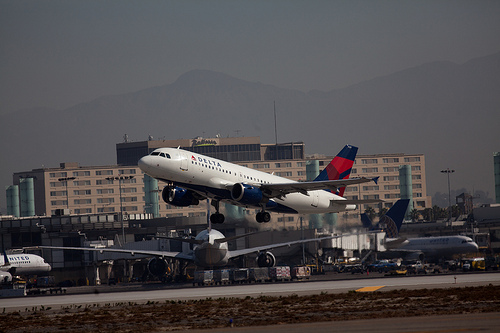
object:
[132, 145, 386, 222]
plane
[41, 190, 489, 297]
gate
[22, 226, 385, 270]
commercial airplane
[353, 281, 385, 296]
stripe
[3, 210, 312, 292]
building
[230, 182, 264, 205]
engine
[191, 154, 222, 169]
brand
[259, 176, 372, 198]
wing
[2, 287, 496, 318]
ground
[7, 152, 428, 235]
building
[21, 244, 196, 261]
item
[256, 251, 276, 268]
wheel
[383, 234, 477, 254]
airplane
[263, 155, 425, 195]
wall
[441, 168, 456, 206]
lights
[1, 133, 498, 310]
airport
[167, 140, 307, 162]
tower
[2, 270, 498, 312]
runway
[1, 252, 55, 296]
plane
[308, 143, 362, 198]
tail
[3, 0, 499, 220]
sky